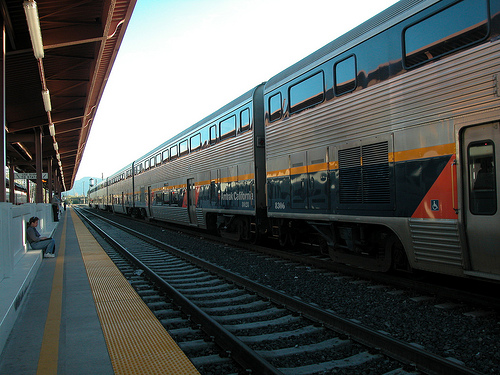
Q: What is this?
A: Train.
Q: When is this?
A: Daytime.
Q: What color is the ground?
A: Gray.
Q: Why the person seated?
A: Resting.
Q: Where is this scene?
A: At a train station.